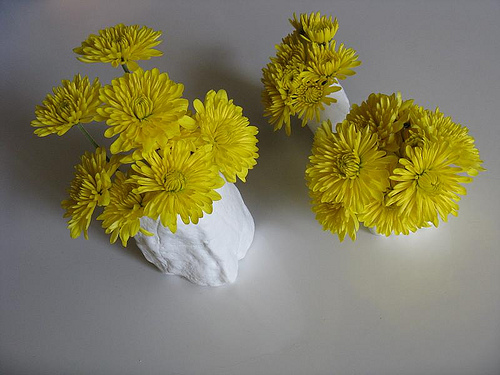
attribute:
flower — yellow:
[288, 9, 342, 41]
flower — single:
[306, 122, 398, 214]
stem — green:
[109, 53, 139, 76]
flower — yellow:
[271, 28, 321, 111]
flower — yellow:
[284, 9, 343, 45]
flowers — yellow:
[36, 9, 485, 251]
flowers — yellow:
[322, 114, 467, 220]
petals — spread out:
[353, 155, 388, 177]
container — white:
[133, 171, 256, 287]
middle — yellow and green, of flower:
[125, 90, 157, 115]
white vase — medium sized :
[134, 178, 258, 295]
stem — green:
[71, 122, 121, 173]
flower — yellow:
[51, 39, 259, 227]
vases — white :
[132, 189, 272, 326]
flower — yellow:
[312, 102, 489, 234]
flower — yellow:
[26, 70, 111, 142]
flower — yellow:
[307, 120, 394, 206]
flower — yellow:
[387, 142, 467, 222]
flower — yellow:
[289, 70, 339, 125]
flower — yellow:
[96, 67, 193, 162]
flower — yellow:
[52, 147, 118, 237]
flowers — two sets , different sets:
[254, 10, 486, 244]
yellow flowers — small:
[300, 113, 433, 226]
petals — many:
[96, 61, 193, 106]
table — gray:
[4, 4, 498, 372]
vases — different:
[119, 167, 257, 290]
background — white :
[13, 288, 493, 371]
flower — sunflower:
[125, 139, 223, 234]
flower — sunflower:
[180, 89, 259, 181]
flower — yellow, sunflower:
[95, 64, 193, 154]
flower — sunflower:
[28, 73, 100, 138]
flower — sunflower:
[71, 20, 163, 67]